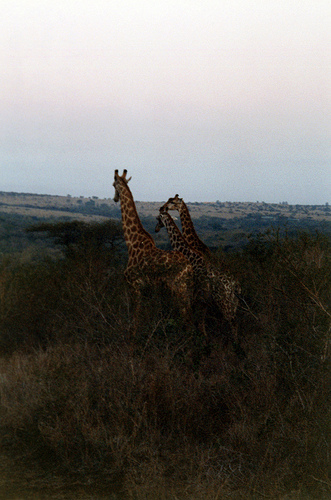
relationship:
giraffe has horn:
[111, 170, 197, 353] [114, 169, 122, 183]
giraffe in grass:
[111, 170, 197, 353] [0, 238, 330, 496]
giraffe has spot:
[111, 170, 197, 353] [136, 236, 144, 246]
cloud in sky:
[16, 83, 325, 187] [4, 0, 329, 208]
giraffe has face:
[111, 170, 197, 353] [111, 179, 122, 200]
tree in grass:
[32, 221, 145, 255] [0, 238, 330, 496]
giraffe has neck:
[111, 170, 197, 353] [117, 189, 154, 258]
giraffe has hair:
[111, 170, 197, 353] [127, 186, 156, 248]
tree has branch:
[32, 221, 145, 255] [103, 234, 116, 250]